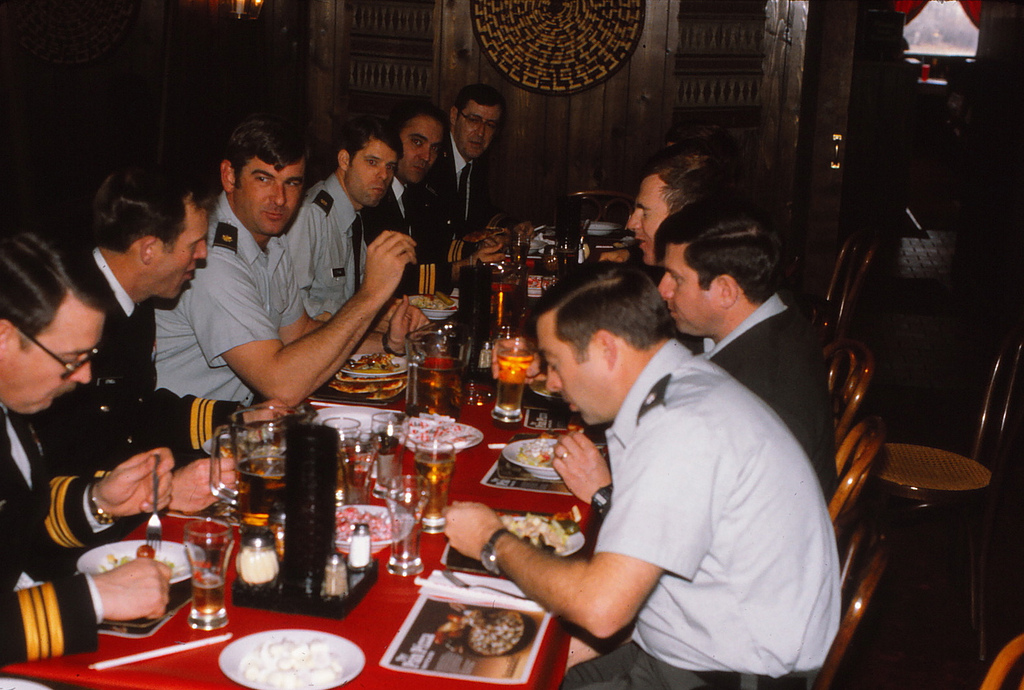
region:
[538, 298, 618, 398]
head of the person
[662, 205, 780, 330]
head of the person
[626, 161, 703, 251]
head of the person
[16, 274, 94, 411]
head of the person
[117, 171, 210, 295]
head of the person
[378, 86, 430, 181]
head of the person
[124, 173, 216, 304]
head of the person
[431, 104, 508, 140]
head of the person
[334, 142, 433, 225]
head of the person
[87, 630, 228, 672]
straw is on top of table cloth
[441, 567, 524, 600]
fork is on top of napkin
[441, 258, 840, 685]
man is sitting down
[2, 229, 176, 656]
man is wearing glasses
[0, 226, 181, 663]
man is holding fork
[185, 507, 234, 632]
glass is in front of plate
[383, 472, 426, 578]
glass is empty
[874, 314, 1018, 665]
chair is empty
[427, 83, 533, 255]
man is wearing glasses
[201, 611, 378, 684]
THIS IS A PLATE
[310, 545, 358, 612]
THIS IS A PEPPER SHAKER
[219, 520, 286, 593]
THIS IS A PARMESAN SHAKER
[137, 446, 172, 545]
THIS IS A FORK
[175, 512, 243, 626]
THIS IS A GLASS OF BEER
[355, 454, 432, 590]
THIS IS AN EMPTY GLASS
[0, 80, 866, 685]
THESE MEN ARE PILOTS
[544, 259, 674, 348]
the hair is black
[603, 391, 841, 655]
the shirt is light blue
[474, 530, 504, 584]
the watch is black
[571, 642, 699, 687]
the pants are grey in color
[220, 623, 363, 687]
a white plate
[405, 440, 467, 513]
a glass of beer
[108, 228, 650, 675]
the table is red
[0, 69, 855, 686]
group of military personnel eating together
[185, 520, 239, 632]
clear drinking glass with beer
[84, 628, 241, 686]
drinking straw wrapped in white paper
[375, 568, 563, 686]
paper place mat with advertisement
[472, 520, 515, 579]
watch on man's left wrist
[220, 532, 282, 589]
Parmesan cheese in shaker container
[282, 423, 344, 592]
lamp light in middle of tray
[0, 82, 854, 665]
a group of military men at a table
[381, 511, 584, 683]
a paper place mat on the table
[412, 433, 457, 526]
a glass of beer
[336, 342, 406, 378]
a bowl of food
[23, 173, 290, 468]
man wearing his dress jacket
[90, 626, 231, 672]
a straw on a red table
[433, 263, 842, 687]
man in a short sleeve shirt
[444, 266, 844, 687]
man with a rounded back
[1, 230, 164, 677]
a man wearing glasses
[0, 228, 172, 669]
a man with a fork in his left hand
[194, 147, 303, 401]
man wearing white uniform and eating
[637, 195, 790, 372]
man wearing blue uniform and eating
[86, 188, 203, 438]
man wearing blue uniform and eating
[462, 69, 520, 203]
man wearing blue uniform and eating